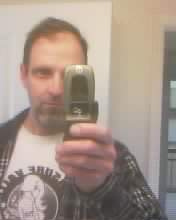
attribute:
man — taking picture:
[6, 22, 151, 219]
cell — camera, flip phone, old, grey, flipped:
[54, 67, 95, 153]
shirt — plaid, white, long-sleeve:
[74, 138, 152, 219]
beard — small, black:
[31, 91, 65, 126]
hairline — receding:
[30, 31, 95, 56]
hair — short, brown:
[18, 10, 96, 60]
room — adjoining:
[155, 20, 172, 219]